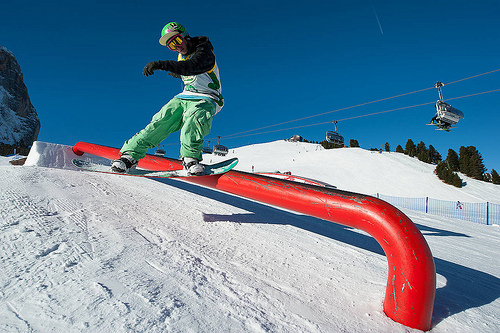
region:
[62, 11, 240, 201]
A snowboarder doing a trick on a rail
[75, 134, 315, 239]
a person snowboarding on a rail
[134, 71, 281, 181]
a person wearing green pants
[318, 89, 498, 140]
a ski lift hovering above a slope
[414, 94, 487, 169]
people sitting in a ski lift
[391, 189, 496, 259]
a net surrounding a ski slope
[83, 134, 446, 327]
a rail attached to a ski slope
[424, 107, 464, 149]
people wearing skis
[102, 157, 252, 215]
a person on top of a snowboard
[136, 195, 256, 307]
snow covering a ski slope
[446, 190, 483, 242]
a person sking down a slope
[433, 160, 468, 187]
tree on snowy hill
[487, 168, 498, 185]
tree on snowy hill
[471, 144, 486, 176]
tree on snowy hill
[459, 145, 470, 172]
tree on snowy hill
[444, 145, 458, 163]
tree on snowy hill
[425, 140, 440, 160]
tree on snowy hill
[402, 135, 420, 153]
tree on snowy hill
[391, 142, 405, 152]
tree on snowy hill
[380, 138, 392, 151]
tree on snowy hill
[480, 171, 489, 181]
tree on snowy hill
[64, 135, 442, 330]
orange metal pole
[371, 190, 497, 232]
blue mesh fence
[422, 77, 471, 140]
ski chair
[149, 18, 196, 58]
green helmet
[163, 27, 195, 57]
red goggles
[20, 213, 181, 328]
marks in snow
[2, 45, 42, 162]
rock structure in snow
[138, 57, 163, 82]
black gloved hand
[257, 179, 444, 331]
red pipe to do tricks on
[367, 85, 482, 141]
ski lift to carry people back to the top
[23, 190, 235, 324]
tracks in the snow from other snowboarders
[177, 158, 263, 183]
the green color of the snow board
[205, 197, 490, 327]
the shadows cast by the sun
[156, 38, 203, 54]
snow goggles to protect eyes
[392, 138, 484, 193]
trees on the side of the mountain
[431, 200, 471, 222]
skier going down the mountain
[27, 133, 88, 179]
a pile of snow